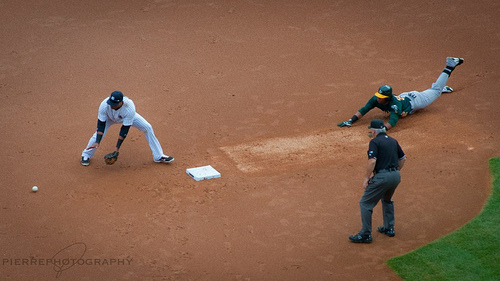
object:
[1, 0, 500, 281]
dirt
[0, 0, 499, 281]
field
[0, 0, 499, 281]
baseball field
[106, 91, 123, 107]
cap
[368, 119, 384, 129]
cap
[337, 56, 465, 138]
baseball player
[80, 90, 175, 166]
uniform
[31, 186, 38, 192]
ball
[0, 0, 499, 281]
ground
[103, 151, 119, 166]
baseball glove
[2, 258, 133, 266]
name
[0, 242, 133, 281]
logo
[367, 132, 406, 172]
black shirt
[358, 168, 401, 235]
gray pants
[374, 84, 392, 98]
helmet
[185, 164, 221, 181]
base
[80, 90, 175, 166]
baseball player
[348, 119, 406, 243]
umpire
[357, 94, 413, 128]
shirt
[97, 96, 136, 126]
shirt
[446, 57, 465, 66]
cleats